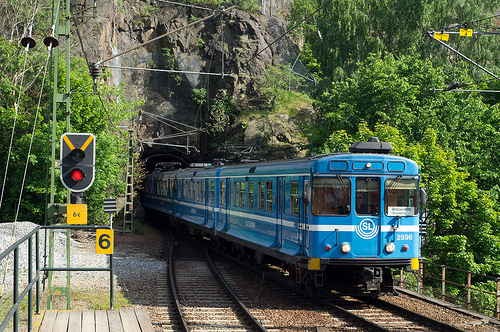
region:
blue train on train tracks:
[135, 140, 435, 305]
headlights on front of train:
[319, 230, 427, 261]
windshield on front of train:
[311, 171, 423, 217]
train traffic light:
[47, 123, 109, 193]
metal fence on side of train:
[1, 205, 120, 330]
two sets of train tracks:
[155, 238, 452, 330]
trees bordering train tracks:
[298, 13, 493, 293]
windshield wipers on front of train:
[331, 172, 358, 212]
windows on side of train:
[170, 176, 305, 211]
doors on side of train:
[271, 172, 286, 250]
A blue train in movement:
[192, 150, 432, 291]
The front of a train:
[309, 142, 426, 276]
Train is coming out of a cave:
[132, 88, 429, 285]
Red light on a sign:
[60, 130, 96, 197]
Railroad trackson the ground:
[163, 250, 269, 328]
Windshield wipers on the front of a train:
[328, 171, 367, 224]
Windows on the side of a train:
[233, 180, 280, 214]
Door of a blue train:
[286, 178, 307, 262]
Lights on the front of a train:
[323, 238, 414, 256]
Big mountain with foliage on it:
[121, 34, 345, 147]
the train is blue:
[145, 127, 440, 301]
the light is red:
[48, 137, 90, 197]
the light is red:
[54, 124, 109, 210]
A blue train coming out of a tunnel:
[111, 122, 441, 319]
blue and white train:
[163, 139, 407, 273]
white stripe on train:
[182, 171, 412, 247]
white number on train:
[391, 229, 413, 249]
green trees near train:
[342, 21, 499, 263]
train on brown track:
[289, 269, 429, 331]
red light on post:
[63, 139, 91, 184]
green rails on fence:
[8, 206, 123, 330]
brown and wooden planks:
[45, 291, 149, 328]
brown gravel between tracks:
[221, 284, 362, 331]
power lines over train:
[69, 9, 405, 115]